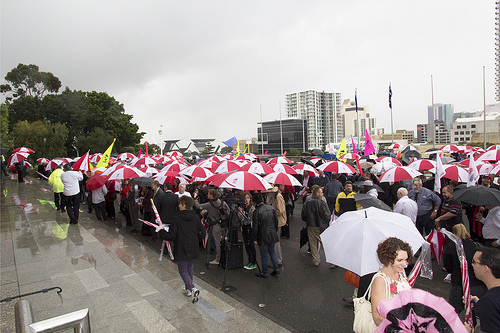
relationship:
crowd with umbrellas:
[75, 143, 461, 265] [139, 149, 341, 188]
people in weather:
[89, 119, 496, 293] [70, 4, 474, 165]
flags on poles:
[384, 82, 394, 109] [385, 85, 394, 144]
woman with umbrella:
[350, 236, 469, 332] [325, 197, 432, 268]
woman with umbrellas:
[350, 236, 469, 332] [139, 149, 341, 188]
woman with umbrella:
[368, 245, 428, 330] [325, 197, 432, 268]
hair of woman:
[381, 244, 407, 255] [368, 245, 428, 330]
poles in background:
[385, 85, 394, 144] [115, 11, 495, 145]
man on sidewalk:
[64, 165, 90, 231] [5, 173, 134, 307]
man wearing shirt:
[64, 165, 90, 231] [59, 172, 91, 196]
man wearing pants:
[64, 165, 90, 231] [62, 196, 84, 224]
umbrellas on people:
[139, 149, 341, 188] [89, 119, 496, 293]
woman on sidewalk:
[161, 187, 219, 287] [5, 173, 134, 307]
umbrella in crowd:
[325, 197, 432, 268] [75, 143, 461, 265]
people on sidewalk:
[4, 151, 105, 224] [5, 173, 134, 307]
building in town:
[258, 130, 305, 158] [248, 75, 484, 150]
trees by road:
[2, 91, 131, 162] [1, 162, 89, 285]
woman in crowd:
[368, 245, 428, 330] [75, 143, 461, 265]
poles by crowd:
[346, 80, 476, 144] [75, 143, 461, 265]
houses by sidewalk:
[161, 126, 230, 158] [5, 173, 134, 307]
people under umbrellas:
[89, 119, 496, 293] [139, 149, 341, 188]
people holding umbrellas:
[89, 119, 496, 293] [139, 149, 341, 188]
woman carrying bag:
[368, 245, 428, 330] [338, 290, 373, 332]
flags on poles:
[339, 60, 402, 113] [346, 80, 476, 144]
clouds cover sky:
[73, 11, 360, 107] [30, 8, 499, 158]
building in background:
[258, 130, 305, 158] [115, 11, 495, 145]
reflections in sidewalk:
[26, 190, 78, 262] [5, 173, 134, 307]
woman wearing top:
[368, 245, 428, 330] [376, 280, 407, 302]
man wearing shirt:
[469, 289, 499, 312] [467, 289, 493, 310]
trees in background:
[2, 91, 131, 162] [115, 11, 495, 145]